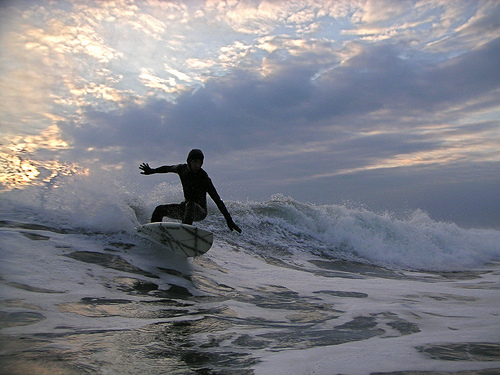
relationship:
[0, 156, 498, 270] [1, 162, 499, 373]
wave in water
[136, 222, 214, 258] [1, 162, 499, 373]
surfboard on water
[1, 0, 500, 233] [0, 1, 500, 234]
clouds in sky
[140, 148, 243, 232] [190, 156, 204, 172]
man has a face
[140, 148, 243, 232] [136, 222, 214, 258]
man on surfboard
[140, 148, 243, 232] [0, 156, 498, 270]
man surfing wave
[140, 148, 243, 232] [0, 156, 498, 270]
man riding wave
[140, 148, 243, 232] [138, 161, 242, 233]
man extending arms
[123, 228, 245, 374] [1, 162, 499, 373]
reflection in water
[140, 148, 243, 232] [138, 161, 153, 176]
man has a right hand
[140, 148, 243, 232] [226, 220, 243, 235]
man has a left hand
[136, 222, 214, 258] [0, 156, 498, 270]
surfboard on wave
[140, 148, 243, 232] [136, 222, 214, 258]
man riding surfboard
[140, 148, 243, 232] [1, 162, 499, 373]
man on water